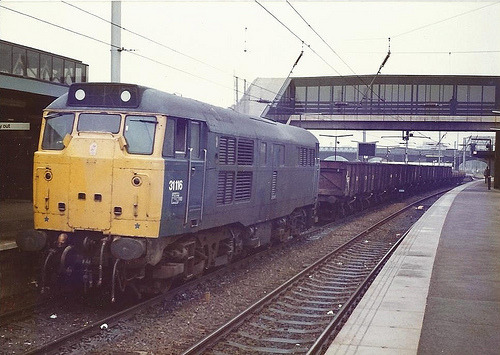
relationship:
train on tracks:
[17, 82, 467, 301] [1, 174, 485, 354]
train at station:
[17, 82, 467, 301] [1, 1, 500, 353]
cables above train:
[0, 0, 499, 171] [17, 82, 467, 301]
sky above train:
[0, 1, 499, 110] [17, 82, 467, 301]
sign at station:
[0, 122, 32, 132] [1, 1, 500, 353]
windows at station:
[0, 38, 500, 128] [1, 1, 500, 353]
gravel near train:
[1, 173, 485, 354] [17, 82, 467, 301]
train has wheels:
[17, 82, 467, 301] [29, 176, 470, 296]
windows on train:
[39, 110, 203, 160] [17, 82, 467, 301]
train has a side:
[17, 82, 467, 301] [155, 87, 468, 301]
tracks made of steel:
[1, 174, 485, 354] [0, 173, 483, 354]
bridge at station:
[232, 75, 498, 134] [1, 1, 500, 353]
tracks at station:
[1, 174, 485, 354] [1, 1, 500, 353]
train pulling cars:
[17, 82, 467, 301] [318, 160, 466, 225]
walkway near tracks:
[322, 174, 498, 354] [1, 174, 485, 354]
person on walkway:
[484, 167, 491, 185] [322, 174, 498, 354]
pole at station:
[110, 2, 122, 83] [1, 1, 500, 353]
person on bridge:
[447, 95, 459, 114] [232, 75, 498, 134]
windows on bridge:
[267, 75, 499, 123] [232, 75, 498, 134]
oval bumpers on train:
[15, 231, 144, 261] [17, 82, 467, 301]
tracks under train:
[1, 174, 485, 354] [17, 82, 467, 301]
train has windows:
[17, 82, 467, 301] [0, 38, 500, 128]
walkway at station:
[322, 174, 498, 354] [1, 1, 500, 353]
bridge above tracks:
[232, 75, 498, 134] [1, 174, 485, 354]